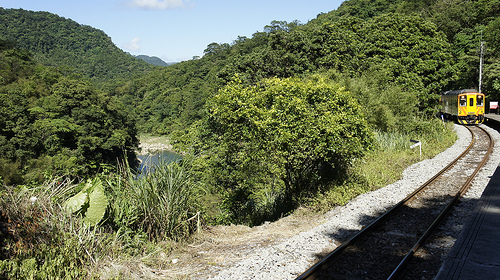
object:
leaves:
[428, 79, 431, 82]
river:
[135, 145, 184, 185]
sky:
[2, 2, 343, 62]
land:
[1, 112, 499, 279]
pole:
[476, 44, 483, 91]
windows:
[459, 95, 467, 107]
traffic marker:
[408, 138, 424, 162]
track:
[388, 163, 482, 275]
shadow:
[297, 184, 499, 278]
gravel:
[277, 265, 280, 267]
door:
[467, 95, 476, 112]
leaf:
[83, 178, 110, 227]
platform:
[431, 195, 498, 279]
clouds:
[20, 0, 340, 48]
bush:
[0, 159, 217, 278]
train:
[432, 88, 486, 127]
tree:
[172, 76, 289, 220]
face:
[457, 93, 486, 123]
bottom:
[463, 120, 479, 125]